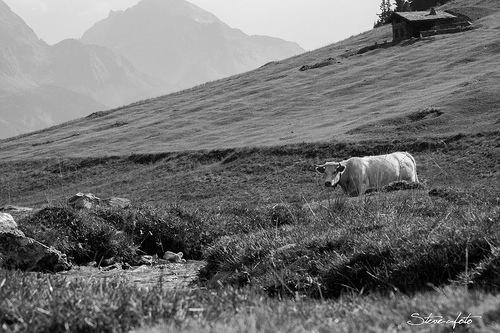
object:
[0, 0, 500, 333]
pasture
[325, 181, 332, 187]
muzzle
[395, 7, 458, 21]
roof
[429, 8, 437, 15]
chimney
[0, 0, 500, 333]
grass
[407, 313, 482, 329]
signature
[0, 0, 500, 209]
slope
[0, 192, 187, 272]
rock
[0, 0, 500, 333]
ground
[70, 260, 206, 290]
water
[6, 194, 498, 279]
bank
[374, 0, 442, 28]
trees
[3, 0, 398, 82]
sky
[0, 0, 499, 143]
background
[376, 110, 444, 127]
crater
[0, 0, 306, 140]
mountains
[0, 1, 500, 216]
hill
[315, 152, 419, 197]
cow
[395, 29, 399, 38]
windows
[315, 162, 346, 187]
head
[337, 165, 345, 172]
cow's ears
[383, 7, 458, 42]
cabin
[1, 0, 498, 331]
picture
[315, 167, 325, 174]
ear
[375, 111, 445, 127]
pit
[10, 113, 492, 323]
field